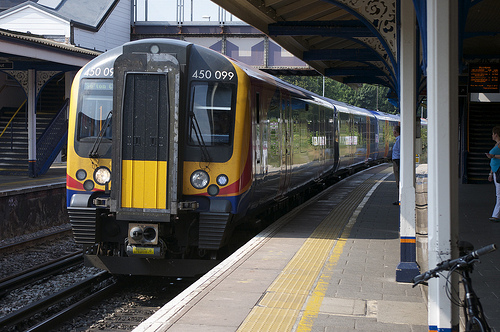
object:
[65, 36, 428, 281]
train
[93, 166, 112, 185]
light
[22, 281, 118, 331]
track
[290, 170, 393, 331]
stripes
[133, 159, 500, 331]
ground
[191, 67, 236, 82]
450 099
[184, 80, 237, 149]
window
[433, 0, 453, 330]
pole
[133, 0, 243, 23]
sky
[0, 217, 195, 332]
gravel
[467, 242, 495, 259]
handlebars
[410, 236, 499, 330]
bike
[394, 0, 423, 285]
posts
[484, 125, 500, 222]
woman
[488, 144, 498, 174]
shirt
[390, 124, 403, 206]
man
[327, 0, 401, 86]
lattice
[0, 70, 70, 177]
stairway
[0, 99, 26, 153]
rail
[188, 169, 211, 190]
haeadlights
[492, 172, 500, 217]
pants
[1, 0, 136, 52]
building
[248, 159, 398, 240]
shadow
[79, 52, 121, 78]
reflection